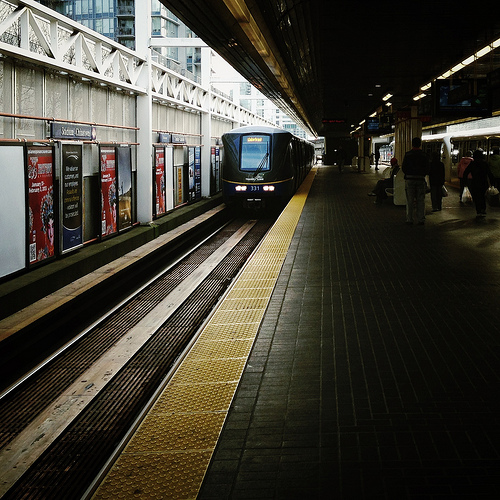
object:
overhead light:
[474, 43, 494, 59]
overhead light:
[368, 111, 376, 117]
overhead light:
[359, 119, 366, 126]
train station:
[0, 0, 500, 500]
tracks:
[0, 210, 273, 500]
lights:
[412, 92, 427, 103]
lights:
[382, 93, 394, 102]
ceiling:
[160, 0, 500, 139]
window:
[239, 133, 272, 172]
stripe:
[220, 177, 293, 185]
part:
[86, 165, 319, 500]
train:
[221, 125, 316, 220]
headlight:
[268, 185, 275, 191]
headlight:
[263, 185, 269, 191]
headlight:
[241, 185, 247, 191]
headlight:
[235, 185, 242, 192]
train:
[372, 126, 500, 179]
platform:
[87, 164, 500, 500]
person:
[463, 147, 496, 218]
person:
[401, 136, 430, 226]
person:
[456, 150, 474, 202]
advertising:
[27, 148, 55, 265]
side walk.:
[197, 165, 500, 500]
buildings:
[186, 25, 201, 79]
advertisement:
[100, 146, 118, 238]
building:
[49, 0, 186, 72]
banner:
[187, 145, 195, 192]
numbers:
[253, 185, 257, 191]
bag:
[484, 185, 500, 197]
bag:
[461, 186, 474, 204]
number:
[250, 185, 253, 192]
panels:
[0, 141, 28, 284]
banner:
[152, 143, 168, 219]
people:
[427, 150, 446, 213]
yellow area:
[90, 167, 318, 500]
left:
[36, 0, 203, 92]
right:
[446, 117, 500, 215]